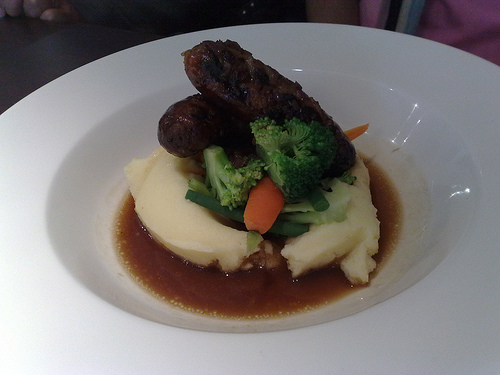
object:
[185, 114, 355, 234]
vegetable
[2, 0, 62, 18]
knuckles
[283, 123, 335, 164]
floret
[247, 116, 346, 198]
broccoli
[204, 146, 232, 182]
stem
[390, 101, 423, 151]
reflection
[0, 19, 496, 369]
bowl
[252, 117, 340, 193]
broccoli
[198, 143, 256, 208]
broccoli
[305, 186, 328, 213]
bean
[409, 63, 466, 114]
plate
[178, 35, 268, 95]
sausage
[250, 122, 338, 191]
steamed brocolli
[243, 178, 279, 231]
carrot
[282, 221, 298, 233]
green beans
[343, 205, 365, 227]
mashed potatoes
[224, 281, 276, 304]
gravy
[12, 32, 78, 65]
table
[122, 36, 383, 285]
food